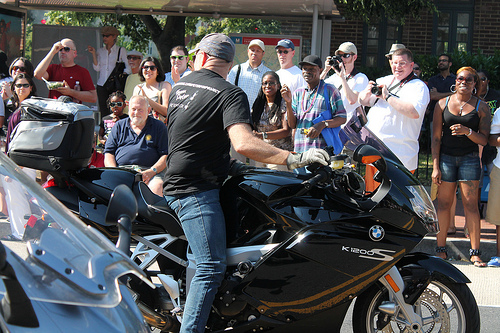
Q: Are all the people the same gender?
A: No, they are both male and female.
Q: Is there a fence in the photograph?
A: No, there are no fences.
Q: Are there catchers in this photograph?
A: No, there are no catchers.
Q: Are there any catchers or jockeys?
A: No, there are no catchers or jockeys.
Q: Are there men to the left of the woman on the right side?
A: Yes, there is a man to the left of the woman.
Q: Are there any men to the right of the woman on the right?
A: No, the man is to the left of the woman.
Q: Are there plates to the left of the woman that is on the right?
A: No, there is a man to the left of the woman.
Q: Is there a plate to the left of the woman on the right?
A: No, there is a man to the left of the woman.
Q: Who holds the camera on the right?
A: The man holds the camera.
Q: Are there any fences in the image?
A: No, there are no fences.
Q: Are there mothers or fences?
A: No, there are no fences or mothers.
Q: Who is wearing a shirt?
A: The man is wearing a shirt.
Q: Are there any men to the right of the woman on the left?
A: Yes, there is a man to the right of the woman.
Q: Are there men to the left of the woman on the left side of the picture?
A: No, the man is to the right of the woman.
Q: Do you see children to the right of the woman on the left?
A: No, there is a man to the right of the woman.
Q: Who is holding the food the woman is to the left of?
A: The man is holding the salad.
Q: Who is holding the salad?
A: The man is holding the salad.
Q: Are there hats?
A: Yes, there is a hat.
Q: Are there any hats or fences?
A: Yes, there is a hat.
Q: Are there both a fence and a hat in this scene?
A: No, there is a hat but no fences.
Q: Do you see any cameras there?
A: Yes, there is a camera.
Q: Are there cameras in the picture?
A: Yes, there is a camera.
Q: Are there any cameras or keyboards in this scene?
A: Yes, there is a camera.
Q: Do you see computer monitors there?
A: No, there are no computer monitors.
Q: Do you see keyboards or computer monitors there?
A: No, there are no computer monitors or keyboards.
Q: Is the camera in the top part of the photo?
A: Yes, the camera is in the top of the image.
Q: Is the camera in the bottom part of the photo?
A: No, the camera is in the top of the image.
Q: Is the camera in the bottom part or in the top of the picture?
A: The camera is in the top of the image.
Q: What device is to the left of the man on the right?
A: The device is a camera.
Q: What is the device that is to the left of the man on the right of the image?
A: The device is a camera.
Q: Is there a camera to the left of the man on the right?
A: Yes, there is a camera to the left of the man.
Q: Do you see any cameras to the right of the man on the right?
A: No, the camera is to the left of the man.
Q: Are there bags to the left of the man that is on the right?
A: No, there is a camera to the left of the man.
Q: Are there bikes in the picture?
A: Yes, there is a bike.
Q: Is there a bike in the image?
A: Yes, there is a bike.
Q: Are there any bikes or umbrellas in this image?
A: Yes, there is a bike.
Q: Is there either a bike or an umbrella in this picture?
A: Yes, there is a bike.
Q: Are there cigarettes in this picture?
A: No, there are no cigarettes.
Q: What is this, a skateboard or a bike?
A: This is a bike.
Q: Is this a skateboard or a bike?
A: This is a bike.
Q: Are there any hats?
A: Yes, there is a hat.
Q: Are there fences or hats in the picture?
A: Yes, there is a hat.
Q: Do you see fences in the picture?
A: No, there are no fences.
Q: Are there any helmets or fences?
A: No, there are no fences or helmets.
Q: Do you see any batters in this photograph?
A: No, there are no batters.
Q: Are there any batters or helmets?
A: No, there are no batters or helmets.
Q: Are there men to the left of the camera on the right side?
A: Yes, there is a man to the left of the camera.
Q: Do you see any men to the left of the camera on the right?
A: Yes, there is a man to the left of the camera.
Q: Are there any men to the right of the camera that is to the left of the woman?
A: No, the man is to the left of the camera.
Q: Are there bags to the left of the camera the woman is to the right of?
A: No, there is a man to the left of the camera.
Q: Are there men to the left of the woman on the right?
A: Yes, there is a man to the left of the woman.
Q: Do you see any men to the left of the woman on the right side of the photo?
A: Yes, there is a man to the left of the woman.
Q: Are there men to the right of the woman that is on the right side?
A: No, the man is to the left of the woman.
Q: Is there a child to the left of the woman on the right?
A: No, there is a man to the left of the woman.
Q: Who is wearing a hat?
A: The man is wearing a hat.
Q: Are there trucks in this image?
A: No, there are no trucks.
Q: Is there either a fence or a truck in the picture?
A: No, there are no trucks or fences.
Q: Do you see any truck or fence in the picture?
A: No, there are no trucks or fences.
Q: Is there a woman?
A: Yes, there is a woman.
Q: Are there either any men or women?
A: Yes, there is a woman.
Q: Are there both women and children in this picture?
A: No, there is a woman but no children.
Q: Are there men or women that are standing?
A: Yes, the woman is standing.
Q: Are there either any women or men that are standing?
A: Yes, the woman is standing.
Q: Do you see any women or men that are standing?
A: Yes, the woman is standing.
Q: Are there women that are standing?
A: Yes, there is a woman that is standing.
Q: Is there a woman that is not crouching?
A: Yes, there is a woman that is standing.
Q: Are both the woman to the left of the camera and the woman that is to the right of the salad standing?
A: Yes, both the woman and the woman are standing.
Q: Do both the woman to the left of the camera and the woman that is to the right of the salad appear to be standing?
A: Yes, both the woman and the woman are standing.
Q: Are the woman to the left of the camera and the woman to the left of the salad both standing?
A: Yes, both the woman and the woman are standing.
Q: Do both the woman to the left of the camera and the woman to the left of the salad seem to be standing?
A: Yes, both the woman and the woman are standing.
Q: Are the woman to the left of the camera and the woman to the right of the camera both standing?
A: Yes, both the woman and the woman are standing.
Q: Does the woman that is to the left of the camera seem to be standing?
A: Yes, the woman is standing.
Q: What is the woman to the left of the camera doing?
A: The woman is standing.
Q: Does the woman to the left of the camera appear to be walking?
A: No, the woman is standing.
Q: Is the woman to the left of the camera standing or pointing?
A: The woman is standing.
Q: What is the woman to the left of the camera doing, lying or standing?
A: The woman is standing.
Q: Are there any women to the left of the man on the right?
A: Yes, there is a woman to the left of the man.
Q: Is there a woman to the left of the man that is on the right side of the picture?
A: Yes, there is a woman to the left of the man.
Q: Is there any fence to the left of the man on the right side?
A: No, there is a woman to the left of the man.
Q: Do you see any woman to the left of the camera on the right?
A: Yes, there is a woman to the left of the camera.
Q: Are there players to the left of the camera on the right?
A: No, there is a woman to the left of the camera.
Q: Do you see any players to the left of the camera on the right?
A: No, there is a woman to the left of the camera.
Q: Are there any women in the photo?
A: Yes, there is a woman.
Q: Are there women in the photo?
A: Yes, there is a woman.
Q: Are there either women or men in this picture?
A: Yes, there is a woman.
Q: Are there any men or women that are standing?
A: Yes, the woman is standing.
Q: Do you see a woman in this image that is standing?
A: Yes, there is a woman that is standing.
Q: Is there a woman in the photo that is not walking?
A: Yes, there is a woman that is standing.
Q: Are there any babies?
A: No, there are no babies.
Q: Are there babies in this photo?
A: No, there are no babies.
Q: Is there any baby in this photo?
A: No, there are no babies.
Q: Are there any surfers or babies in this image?
A: No, there are no babies or surfers.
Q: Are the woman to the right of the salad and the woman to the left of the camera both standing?
A: Yes, both the woman and the woman are standing.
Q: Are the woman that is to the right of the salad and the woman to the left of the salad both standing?
A: Yes, both the woman and the woman are standing.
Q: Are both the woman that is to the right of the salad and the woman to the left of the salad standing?
A: Yes, both the woman and the woman are standing.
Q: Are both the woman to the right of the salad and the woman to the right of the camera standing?
A: Yes, both the woman and the woman are standing.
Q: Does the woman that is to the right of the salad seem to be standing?
A: Yes, the woman is standing.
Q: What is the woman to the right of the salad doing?
A: The woman is standing.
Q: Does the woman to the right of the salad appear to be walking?
A: No, the woman is standing.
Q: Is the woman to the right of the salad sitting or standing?
A: The woman is standing.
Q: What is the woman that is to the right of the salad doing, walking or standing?
A: The woman is standing.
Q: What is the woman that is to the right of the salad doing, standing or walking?
A: The woman is standing.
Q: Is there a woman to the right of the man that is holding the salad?
A: Yes, there is a woman to the right of the man.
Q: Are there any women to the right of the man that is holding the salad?
A: Yes, there is a woman to the right of the man.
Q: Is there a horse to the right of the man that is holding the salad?
A: No, there is a woman to the right of the man.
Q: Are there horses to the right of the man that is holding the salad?
A: No, there is a woman to the right of the man.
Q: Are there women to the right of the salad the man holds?
A: Yes, there is a woman to the right of the salad.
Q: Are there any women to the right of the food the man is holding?
A: Yes, there is a woman to the right of the salad.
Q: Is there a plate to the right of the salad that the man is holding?
A: No, there is a woman to the right of the salad.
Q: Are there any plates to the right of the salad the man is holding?
A: No, there is a woman to the right of the salad.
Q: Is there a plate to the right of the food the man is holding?
A: No, there is a woman to the right of the salad.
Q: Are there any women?
A: Yes, there is a woman.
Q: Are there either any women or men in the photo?
A: Yes, there is a woman.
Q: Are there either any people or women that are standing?
A: Yes, the woman is standing.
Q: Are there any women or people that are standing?
A: Yes, the woman is standing.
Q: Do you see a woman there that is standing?
A: Yes, there is a woman that is standing.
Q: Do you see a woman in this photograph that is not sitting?
A: Yes, there is a woman that is standing .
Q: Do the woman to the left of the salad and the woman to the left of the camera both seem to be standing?
A: Yes, both the woman and the woman are standing.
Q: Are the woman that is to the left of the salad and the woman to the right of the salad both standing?
A: Yes, both the woman and the woman are standing.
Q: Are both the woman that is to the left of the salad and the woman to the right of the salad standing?
A: Yes, both the woman and the woman are standing.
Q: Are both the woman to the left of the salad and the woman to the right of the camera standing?
A: Yes, both the woman and the woman are standing.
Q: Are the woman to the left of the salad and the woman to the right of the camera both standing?
A: Yes, both the woman and the woman are standing.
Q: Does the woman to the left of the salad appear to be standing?
A: Yes, the woman is standing.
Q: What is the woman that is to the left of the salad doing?
A: The woman is standing.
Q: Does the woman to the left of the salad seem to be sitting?
A: No, the woman is standing.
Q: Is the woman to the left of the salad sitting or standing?
A: The woman is standing.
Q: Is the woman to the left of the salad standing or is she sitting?
A: The woman is standing.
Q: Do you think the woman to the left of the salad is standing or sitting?
A: The woman is standing.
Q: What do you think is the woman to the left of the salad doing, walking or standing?
A: The woman is standing.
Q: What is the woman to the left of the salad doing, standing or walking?
A: The woman is standing.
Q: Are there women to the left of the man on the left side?
A: Yes, there is a woman to the left of the man.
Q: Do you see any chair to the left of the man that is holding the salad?
A: No, there is a woman to the left of the man.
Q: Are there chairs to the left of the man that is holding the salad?
A: No, there is a woman to the left of the man.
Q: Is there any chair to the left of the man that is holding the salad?
A: No, there is a woman to the left of the man.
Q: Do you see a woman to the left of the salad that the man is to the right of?
A: Yes, there is a woman to the left of the salad.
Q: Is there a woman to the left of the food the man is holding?
A: Yes, there is a woman to the left of the salad.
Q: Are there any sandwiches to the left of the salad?
A: No, there is a woman to the left of the salad.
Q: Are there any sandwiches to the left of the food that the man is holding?
A: No, there is a woman to the left of the salad.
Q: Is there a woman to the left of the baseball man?
A: Yes, there is a woman to the left of the man.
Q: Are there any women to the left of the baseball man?
A: Yes, there is a woman to the left of the man.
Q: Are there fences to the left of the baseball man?
A: No, there is a woman to the left of the man.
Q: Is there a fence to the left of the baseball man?
A: No, there is a woman to the left of the man.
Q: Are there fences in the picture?
A: No, there are no fences.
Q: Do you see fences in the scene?
A: No, there are no fences.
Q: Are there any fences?
A: No, there are no fences.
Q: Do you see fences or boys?
A: No, there are no fences or boys.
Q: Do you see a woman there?
A: Yes, there is a woman.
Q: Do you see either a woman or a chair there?
A: Yes, there is a woman.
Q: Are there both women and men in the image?
A: Yes, there are both a woman and a man.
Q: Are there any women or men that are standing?
A: Yes, the woman is standing.